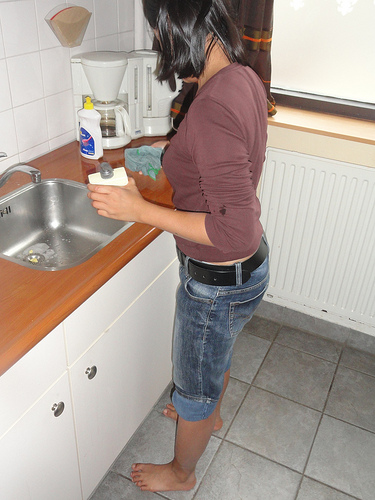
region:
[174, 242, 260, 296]
lady wearing black belt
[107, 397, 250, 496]
lady is barefoot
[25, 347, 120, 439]
2 chrome knobs on door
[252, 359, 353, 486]
clean gray tiles on ground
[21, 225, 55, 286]
yellow items in the sink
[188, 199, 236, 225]
dark stain on ladies shirt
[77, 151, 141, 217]
lady holding soap dispenser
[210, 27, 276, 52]
orange and red curtains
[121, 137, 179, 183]
lady is holding sponge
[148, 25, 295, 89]
lady has short black hair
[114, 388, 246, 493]
she is barefoot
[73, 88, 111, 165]
a white bottle of dishsoap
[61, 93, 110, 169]
bottle of dish liquid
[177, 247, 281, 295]
a black belt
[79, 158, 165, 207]
a bottle of soap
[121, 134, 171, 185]
a green dish towel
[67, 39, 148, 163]
a white coffee maker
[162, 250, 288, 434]
a pair of blue jeans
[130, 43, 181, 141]
a hot water boiler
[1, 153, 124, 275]
a sink with soapy water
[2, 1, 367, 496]
Woman using cleaner in kitchen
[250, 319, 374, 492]
Tile floor in Kitchen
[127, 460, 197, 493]
Adult Woman's Left Bare Foot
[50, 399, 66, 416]
Kitchen Cabinet Knob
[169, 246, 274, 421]
Adult Woman's Rolled Up Denim Blue Jeans with Belt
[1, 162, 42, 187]
Stainless Steel Kitchen Faucet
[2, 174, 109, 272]
Stainless Steel Kitchen Sink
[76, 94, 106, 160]
Kitchen Dish Soap or Cleanser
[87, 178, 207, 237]
Adult Woman's Left Arm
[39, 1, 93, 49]
Hanging Coffee Filter Holder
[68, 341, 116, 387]
a handle on a cabinet door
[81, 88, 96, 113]
a yellow lid on a bottle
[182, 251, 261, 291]
a woman wearing a black belt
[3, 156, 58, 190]
a faucet in the kitchen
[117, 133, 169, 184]
a rag in the womans hand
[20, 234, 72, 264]
a sink in the kitchen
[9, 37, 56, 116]
white tile on the kitchen wall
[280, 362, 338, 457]
tile on the kitchen floor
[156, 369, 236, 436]
a woman wearing rolled up blue jeans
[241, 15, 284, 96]
curtains in a kitchen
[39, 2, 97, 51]
Paper coffee filters on kitchen wall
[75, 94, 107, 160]
Dish soap bottle on kitchen counter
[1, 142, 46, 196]
Metal silver kitchen faucet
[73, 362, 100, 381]
Metal knob on kitchen cabinet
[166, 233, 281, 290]
Girl wearing black belt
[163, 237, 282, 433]
Girl wearing blue jeans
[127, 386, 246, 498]
Bare feet on kitchen floor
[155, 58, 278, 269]
Girl wearing long sleeve sweater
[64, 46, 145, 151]
Coffee pot on kitchen counter top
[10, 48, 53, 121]
White tile on kitchen wall